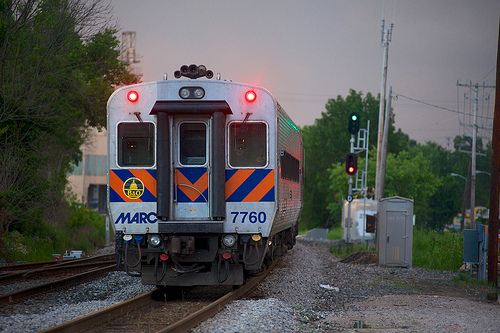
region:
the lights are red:
[120, 82, 275, 121]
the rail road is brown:
[52, 255, 211, 327]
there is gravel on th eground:
[293, 256, 318, 332]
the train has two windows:
[128, 124, 278, 170]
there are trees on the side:
[8, 31, 100, 261]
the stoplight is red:
[337, 161, 377, 185]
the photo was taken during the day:
[31, 36, 482, 332]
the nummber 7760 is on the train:
[232, 211, 278, 231]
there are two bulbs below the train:
[142, 227, 251, 255]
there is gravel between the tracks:
[73, 283, 125, 300]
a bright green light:
[347, 107, 367, 143]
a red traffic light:
[341, 147, 362, 183]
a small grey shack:
[365, 186, 420, 287]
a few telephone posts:
[439, 55, 489, 227]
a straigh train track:
[306, 217, 338, 259]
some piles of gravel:
[255, 284, 304, 326]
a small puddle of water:
[342, 308, 376, 331]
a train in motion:
[74, 57, 369, 330]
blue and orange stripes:
[97, 165, 274, 208]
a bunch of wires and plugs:
[113, 230, 267, 273]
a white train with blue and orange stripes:
[97, 56, 308, 296]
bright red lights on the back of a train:
[115, 82, 268, 107]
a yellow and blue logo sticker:
[120, 175, 146, 201]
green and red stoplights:
[339, 103, 373, 264]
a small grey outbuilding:
[372, 188, 419, 275]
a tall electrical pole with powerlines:
[450, 68, 498, 226]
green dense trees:
[1, 2, 97, 255]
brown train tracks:
[2, 261, 277, 332]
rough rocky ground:
[276, 268, 456, 331]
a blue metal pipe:
[456, 215, 490, 286]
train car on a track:
[100, 62, 302, 286]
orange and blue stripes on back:
[105, 166, 279, 206]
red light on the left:
[125, 87, 140, 105]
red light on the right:
[244, 88, 256, 98]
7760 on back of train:
[231, 208, 269, 224]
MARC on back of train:
[113, 209, 158, 224]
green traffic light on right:
[343, 111, 360, 136]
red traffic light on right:
[341, 151, 357, 175]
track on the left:
[3, 242, 123, 296]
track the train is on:
[51, 284, 251, 331]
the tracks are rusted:
[73, 269, 271, 328]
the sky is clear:
[192, 9, 338, 74]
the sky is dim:
[193, 4, 347, 77]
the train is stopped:
[67, 22, 332, 322]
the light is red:
[340, 138, 361, 183]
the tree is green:
[21, 33, 88, 178]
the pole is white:
[371, 19, 399, 218]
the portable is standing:
[367, 187, 418, 282]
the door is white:
[368, 191, 423, 277]